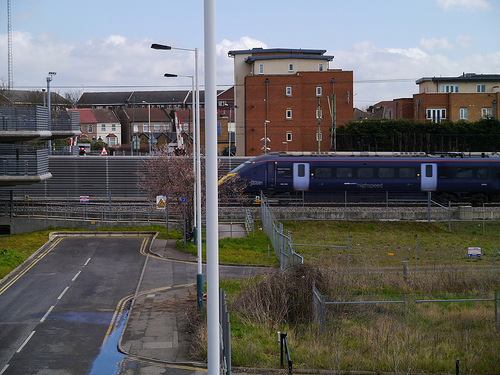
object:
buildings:
[365, 73, 500, 122]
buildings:
[74, 86, 235, 154]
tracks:
[15, 199, 494, 209]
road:
[0, 213, 182, 375]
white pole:
[193, 45, 203, 272]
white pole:
[228, 105, 232, 155]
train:
[204, 153, 500, 208]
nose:
[200, 159, 261, 205]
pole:
[265, 78, 270, 151]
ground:
[0, 214, 500, 375]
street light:
[149, 41, 204, 312]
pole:
[203, 0, 219, 375]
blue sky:
[0, 0, 500, 101]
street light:
[162, 67, 197, 258]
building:
[228, 47, 355, 156]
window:
[316, 87, 321, 96]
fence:
[256, 190, 496, 341]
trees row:
[334, 115, 500, 151]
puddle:
[89, 308, 132, 375]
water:
[97, 355, 114, 373]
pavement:
[5, 232, 147, 374]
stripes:
[84, 257, 91, 266]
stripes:
[70, 269, 84, 281]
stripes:
[57, 283, 73, 299]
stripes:
[40, 303, 57, 323]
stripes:
[16, 330, 37, 351]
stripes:
[0, 357, 11, 375]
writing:
[357, 182, 384, 189]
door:
[293, 161, 310, 191]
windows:
[314, 166, 415, 180]